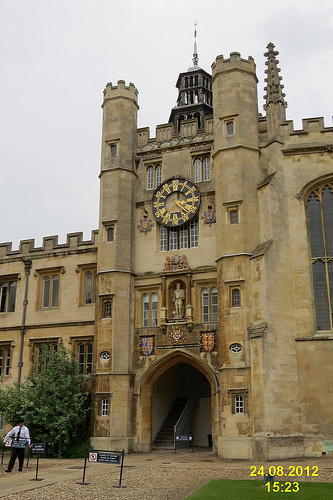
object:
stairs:
[153, 397, 191, 450]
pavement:
[0, 450, 332, 499]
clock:
[151, 174, 200, 225]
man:
[2, 421, 31, 468]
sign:
[12, 439, 28, 449]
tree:
[0, 337, 98, 460]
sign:
[87, 449, 120, 463]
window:
[235, 395, 244, 414]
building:
[0, 22, 333, 460]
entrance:
[136, 348, 218, 455]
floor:
[0, 454, 333, 500]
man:
[4, 412, 43, 482]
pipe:
[14, 282, 28, 390]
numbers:
[149, 174, 202, 231]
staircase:
[152, 391, 197, 454]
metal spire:
[186, 20, 200, 66]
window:
[303, 180, 333, 332]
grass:
[183, 478, 333, 500]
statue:
[172, 282, 184, 317]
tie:
[17, 427, 21, 442]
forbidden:
[89, 452, 98, 463]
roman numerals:
[148, 172, 203, 228]